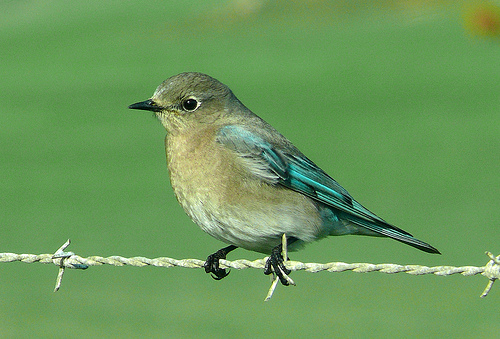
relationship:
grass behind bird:
[4, 2, 496, 338] [116, 63, 448, 292]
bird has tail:
[116, 63, 448, 292] [329, 184, 445, 257]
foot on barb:
[263, 255, 292, 287] [263, 228, 300, 305]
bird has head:
[116, 63, 448, 292] [131, 68, 243, 132]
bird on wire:
[127, 71, 441, 287] [4, 251, 498, 274]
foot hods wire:
[203, 252, 231, 281] [140, 255, 310, 284]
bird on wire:
[127, 71, 441, 287] [81, 251, 400, 287]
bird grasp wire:
[127, 71, 441, 287] [1, 238, 498, 298]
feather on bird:
[245, 136, 384, 221] [116, 63, 448, 292]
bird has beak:
[127, 71, 441, 287] [122, 94, 165, 117]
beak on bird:
[127, 98, 164, 111] [127, 71, 441, 287]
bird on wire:
[116, 63, 448, 292] [0, 242, 195, 268]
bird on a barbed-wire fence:
[116, 63, 448, 292] [2, 234, 497, 304]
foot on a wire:
[264, 251, 291, 284] [1, 238, 498, 298]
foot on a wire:
[203, 252, 230, 279] [1, 238, 498, 298]